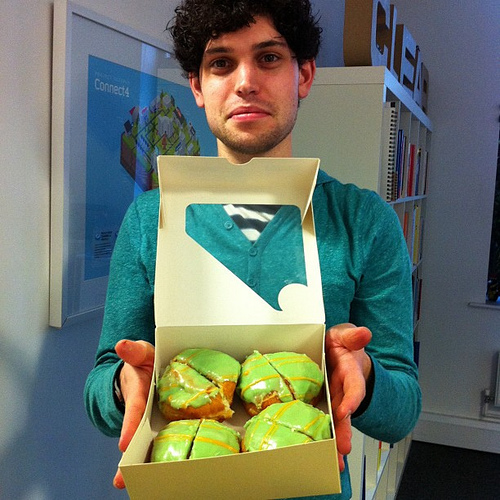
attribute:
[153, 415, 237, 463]
donunt — cut in half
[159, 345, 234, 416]
donunt — cut in half, yummy, in box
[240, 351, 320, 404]
donunt — cut in half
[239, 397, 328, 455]
donunt — cut in half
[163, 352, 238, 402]
frosting — green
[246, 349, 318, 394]
frosting — green, bright green, bright yellow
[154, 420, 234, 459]
frosting — yellow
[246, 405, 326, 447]
frosting — yellow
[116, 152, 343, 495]
box — white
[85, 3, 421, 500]
man — dark haired, young, standing, looking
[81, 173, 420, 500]
henley shirt — blue, green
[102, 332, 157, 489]
hand — clean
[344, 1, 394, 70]
letter — large, brown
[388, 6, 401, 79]
letter — decorative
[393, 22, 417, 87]
letter — decorative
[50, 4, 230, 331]
picture frame — white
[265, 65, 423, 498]
bookshelf — white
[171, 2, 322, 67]
hair — black, curly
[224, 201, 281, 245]
shirt — striped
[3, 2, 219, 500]
wall — white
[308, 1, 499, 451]
wall — white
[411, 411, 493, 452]
moulding — white